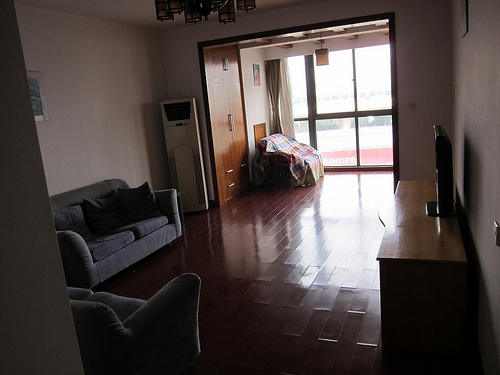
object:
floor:
[215, 205, 372, 369]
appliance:
[156, 97, 211, 211]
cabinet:
[375, 177, 468, 362]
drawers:
[220, 163, 252, 200]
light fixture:
[149, 0, 258, 26]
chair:
[250, 135, 324, 189]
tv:
[425, 121, 456, 236]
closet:
[201, 47, 251, 201]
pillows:
[51, 182, 155, 230]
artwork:
[27, 68, 48, 122]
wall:
[40, 0, 159, 179]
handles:
[227, 114, 236, 133]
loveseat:
[64, 271, 203, 373]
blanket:
[261, 149, 314, 180]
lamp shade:
[200, 4, 209, 13]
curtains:
[264, 60, 282, 137]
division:
[303, 51, 317, 152]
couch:
[43, 177, 185, 289]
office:
[0, 0, 483, 366]